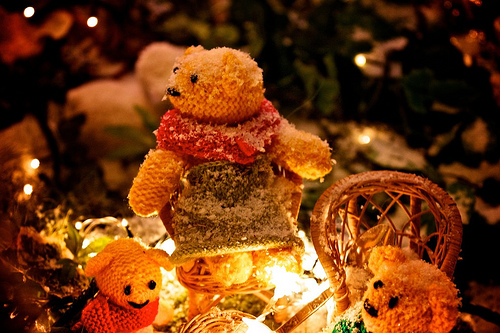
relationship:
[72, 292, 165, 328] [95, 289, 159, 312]
scarf around bear's neck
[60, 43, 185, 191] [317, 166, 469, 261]
bear not in chair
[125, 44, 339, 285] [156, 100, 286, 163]
bear wearing scarf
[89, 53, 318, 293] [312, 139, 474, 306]
bear on chair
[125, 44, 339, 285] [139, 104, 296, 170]
bear with scarf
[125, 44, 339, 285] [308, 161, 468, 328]
bear in chair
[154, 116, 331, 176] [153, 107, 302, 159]
snow on scarf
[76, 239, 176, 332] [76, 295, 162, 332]
bear wearing scarf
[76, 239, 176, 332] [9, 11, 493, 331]
bear looking at camera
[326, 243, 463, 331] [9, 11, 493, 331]
bear looking at camera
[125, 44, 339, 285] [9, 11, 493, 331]
bear looking at camera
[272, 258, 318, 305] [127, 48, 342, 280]
christmas light near yarn bear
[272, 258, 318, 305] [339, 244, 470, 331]
christmas light near yarn bear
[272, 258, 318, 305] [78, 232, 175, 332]
christmas light near yarn bear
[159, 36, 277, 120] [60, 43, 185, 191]
head of bear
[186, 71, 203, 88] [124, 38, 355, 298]
eye of teddy bear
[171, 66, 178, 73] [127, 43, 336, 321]
eye of teddy bear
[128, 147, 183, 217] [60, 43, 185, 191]
arm of bear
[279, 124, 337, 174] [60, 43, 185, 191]
arm of bear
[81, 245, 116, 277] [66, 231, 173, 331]
ear of teddy bear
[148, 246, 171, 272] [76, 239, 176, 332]
ear of bear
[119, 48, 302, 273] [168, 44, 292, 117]
animal on ball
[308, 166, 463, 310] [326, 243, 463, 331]
chair behind bear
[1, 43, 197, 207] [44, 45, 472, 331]
bear behind bears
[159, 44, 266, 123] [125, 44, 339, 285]
head of bear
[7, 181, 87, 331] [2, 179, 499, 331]
flower decoration on table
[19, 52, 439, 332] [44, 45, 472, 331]
piece consists of bears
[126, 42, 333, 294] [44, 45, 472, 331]
decoration consists of bears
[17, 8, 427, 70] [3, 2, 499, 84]
string of lights